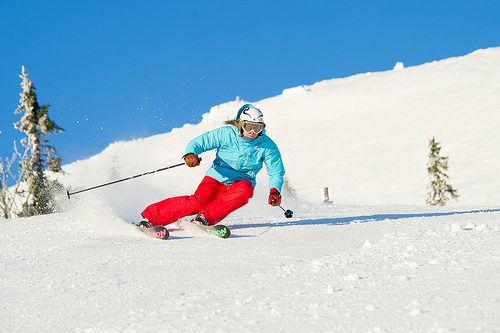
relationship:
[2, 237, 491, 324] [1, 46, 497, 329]
snow on ground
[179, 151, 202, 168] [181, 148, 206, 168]
hand in mitten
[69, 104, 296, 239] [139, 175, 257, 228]
woman wears pants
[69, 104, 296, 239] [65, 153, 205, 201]
woman holds pole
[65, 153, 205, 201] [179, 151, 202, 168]
pole in hand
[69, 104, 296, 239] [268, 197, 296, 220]
woman holds pole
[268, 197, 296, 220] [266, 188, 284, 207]
pole in hand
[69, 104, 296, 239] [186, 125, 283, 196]
woman wears coat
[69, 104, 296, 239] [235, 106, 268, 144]
woman wears helmet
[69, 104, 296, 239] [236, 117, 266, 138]
woman wears goggles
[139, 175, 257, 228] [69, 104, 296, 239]
pants are on woman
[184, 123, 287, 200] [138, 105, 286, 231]
coat on woman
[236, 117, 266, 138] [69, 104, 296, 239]
goggles are on woman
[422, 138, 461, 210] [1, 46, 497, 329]
tree in snow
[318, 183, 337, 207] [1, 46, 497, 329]
marker in snow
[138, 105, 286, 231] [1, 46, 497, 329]
woman in snow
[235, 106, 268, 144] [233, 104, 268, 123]
helmet has patterns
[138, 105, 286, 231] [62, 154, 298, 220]
woman has ski poles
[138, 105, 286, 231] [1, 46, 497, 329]
woman skiing downhill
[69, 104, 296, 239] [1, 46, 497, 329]
woman skiing down slope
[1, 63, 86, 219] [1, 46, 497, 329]
tree covered in snow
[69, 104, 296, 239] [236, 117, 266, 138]
woman wearing sunglasses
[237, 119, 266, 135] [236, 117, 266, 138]
goggles are on sunglasses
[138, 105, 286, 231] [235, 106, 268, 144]
woman has helmet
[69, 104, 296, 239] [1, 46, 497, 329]
woman on slopes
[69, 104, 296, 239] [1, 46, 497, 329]
woman coming slopes